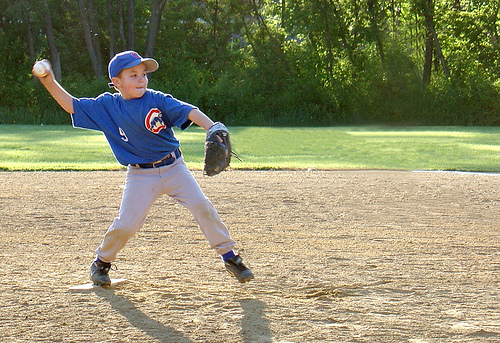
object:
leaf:
[288, 99, 290, 102]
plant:
[255, 76, 344, 126]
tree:
[317, 0, 345, 80]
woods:
[19, 1, 40, 57]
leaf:
[343, 73, 347, 78]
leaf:
[364, 91, 373, 99]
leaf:
[207, 80, 213, 84]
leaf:
[261, 94, 271, 102]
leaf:
[331, 94, 338, 100]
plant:
[429, 68, 500, 126]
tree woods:
[42, 1, 95, 52]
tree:
[141, 0, 168, 58]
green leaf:
[444, 90, 448, 95]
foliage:
[1, 0, 500, 123]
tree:
[413, 0, 441, 99]